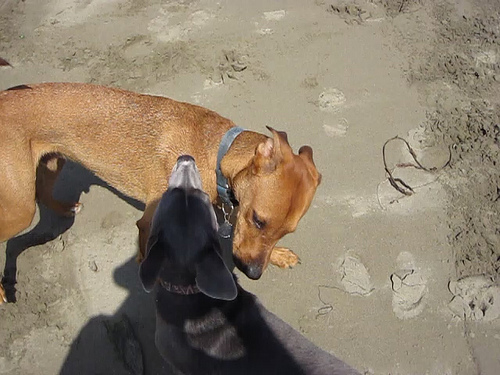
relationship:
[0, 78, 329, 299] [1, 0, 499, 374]
dog standing on beach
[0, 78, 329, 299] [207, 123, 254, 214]
dog has collar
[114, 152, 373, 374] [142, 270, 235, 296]
dog has collar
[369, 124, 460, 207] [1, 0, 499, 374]
branch on beach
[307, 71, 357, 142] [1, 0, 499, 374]
footprints on beach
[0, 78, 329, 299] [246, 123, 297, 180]
dog has ear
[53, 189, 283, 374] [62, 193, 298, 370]
person has shadow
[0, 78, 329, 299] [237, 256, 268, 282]
dog has nose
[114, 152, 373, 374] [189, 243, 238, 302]
dog has ear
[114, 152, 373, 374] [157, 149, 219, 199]
dog has snout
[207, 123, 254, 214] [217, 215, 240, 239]
collar has tag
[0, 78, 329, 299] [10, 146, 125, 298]
dog has shadow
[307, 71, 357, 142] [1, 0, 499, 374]
footprints in beach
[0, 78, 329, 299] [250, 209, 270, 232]
dog has eye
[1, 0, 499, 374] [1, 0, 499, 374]
beach has beach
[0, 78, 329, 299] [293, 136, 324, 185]
dog has ear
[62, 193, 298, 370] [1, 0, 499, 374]
shadow on beach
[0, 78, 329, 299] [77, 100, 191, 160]
dog has fur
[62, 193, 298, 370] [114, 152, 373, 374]
shadow on dog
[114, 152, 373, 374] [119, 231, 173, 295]
dog has ear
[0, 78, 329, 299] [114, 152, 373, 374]
dog smelling dog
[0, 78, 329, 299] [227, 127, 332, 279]
dog has head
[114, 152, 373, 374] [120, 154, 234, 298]
dog has head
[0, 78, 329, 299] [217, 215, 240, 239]
dog has tag